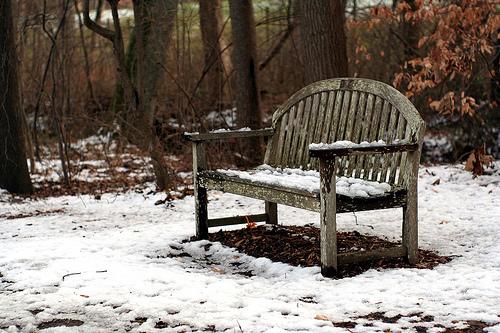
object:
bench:
[183, 78, 427, 276]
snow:
[218, 162, 391, 199]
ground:
[0, 106, 500, 333]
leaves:
[208, 224, 452, 279]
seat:
[198, 166, 408, 214]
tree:
[294, 1, 350, 93]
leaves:
[347, 1, 498, 178]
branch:
[92, 117, 132, 144]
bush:
[0, 0, 498, 201]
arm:
[308, 140, 419, 194]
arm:
[183, 127, 273, 170]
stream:
[74, 0, 432, 24]